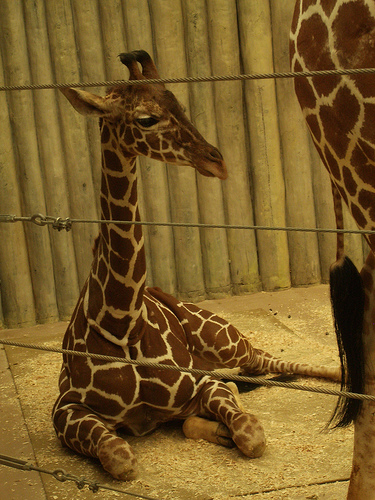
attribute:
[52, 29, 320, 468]
animal — lying down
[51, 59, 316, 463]
giraffe — lying down, tan, baby, brown, on ground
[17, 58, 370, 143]
fence — wire, metal, rope, grey, cable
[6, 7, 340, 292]
wall — wooden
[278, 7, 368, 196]
giraffe — adult, on right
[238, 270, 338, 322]
ground — concrete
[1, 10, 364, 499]
picture — at zoo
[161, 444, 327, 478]
sawdust — on floor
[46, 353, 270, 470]
legs — outstretched, folded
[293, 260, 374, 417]
fur — black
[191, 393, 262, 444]
foot — hoof, hoof-like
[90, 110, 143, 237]
neck — long, brown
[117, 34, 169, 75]
ossicles — horn-like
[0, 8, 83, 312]
poles — wooden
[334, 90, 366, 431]
tail — long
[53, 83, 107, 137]
ear — pointed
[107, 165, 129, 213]
spot — brown